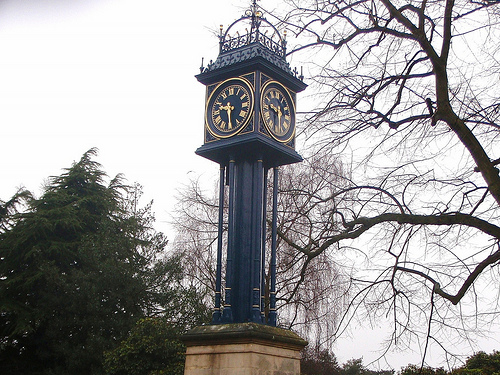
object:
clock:
[203, 77, 254, 140]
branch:
[469, 185, 488, 216]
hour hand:
[217, 103, 235, 110]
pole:
[251, 156, 265, 323]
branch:
[450, 22, 500, 39]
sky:
[0, 1, 500, 374]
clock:
[258, 79, 298, 145]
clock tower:
[180, 0, 309, 374]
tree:
[0, 145, 215, 374]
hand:
[275, 110, 282, 132]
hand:
[269, 103, 282, 115]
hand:
[225, 109, 233, 129]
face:
[211, 84, 249, 128]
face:
[260, 88, 293, 137]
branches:
[294, 0, 369, 38]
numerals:
[237, 109, 247, 118]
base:
[180, 322, 309, 375]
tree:
[164, 0, 499, 374]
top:
[192, 0, 310, 93]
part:
[190, 350, 245, 372]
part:
[463, 260, 490, 289]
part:
[433, 120, 500, 293]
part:
[310, 25, 398, 62]